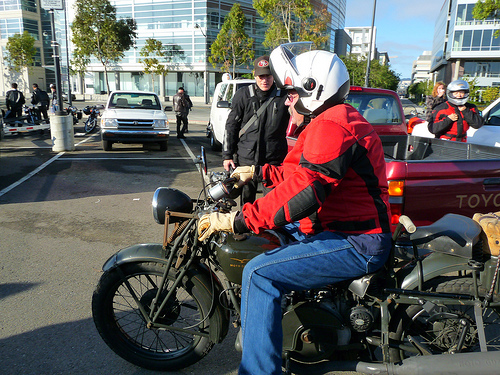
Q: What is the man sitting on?
A: Motorcycle.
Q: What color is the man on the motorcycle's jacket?
A: Red and black.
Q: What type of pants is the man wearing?
A: Blue jeans.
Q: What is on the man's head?
A: Helmet.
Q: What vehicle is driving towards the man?
A: White pickup truck.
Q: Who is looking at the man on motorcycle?
A: Man in black jacket.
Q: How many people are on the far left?
A: Three.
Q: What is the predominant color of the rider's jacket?
A: Red.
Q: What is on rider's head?
A: Helmet.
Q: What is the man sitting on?
A: Motorcycle.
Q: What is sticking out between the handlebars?
A: Headlight.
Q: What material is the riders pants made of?
A: Denim.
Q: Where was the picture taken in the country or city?
A: City.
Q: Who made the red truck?
A: Toyota.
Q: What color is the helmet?
A: White.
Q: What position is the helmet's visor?
A: Up.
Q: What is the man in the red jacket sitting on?
A: Motorcycle.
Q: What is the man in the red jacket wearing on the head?
A: Helmet.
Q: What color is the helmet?
A: White.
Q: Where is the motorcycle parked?
A: Parking lot.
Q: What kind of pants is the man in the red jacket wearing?
A: Jeans.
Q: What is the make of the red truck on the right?
A: Toyota.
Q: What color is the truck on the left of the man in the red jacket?
A: White.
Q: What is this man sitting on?
A: A motorcycle.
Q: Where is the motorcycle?
A: In a parking lot.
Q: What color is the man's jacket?
A: Red.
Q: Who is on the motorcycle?
A: A man.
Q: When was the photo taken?
A: During the day.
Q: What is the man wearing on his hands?
A: Gloves.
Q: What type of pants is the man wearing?
A: Jeans.